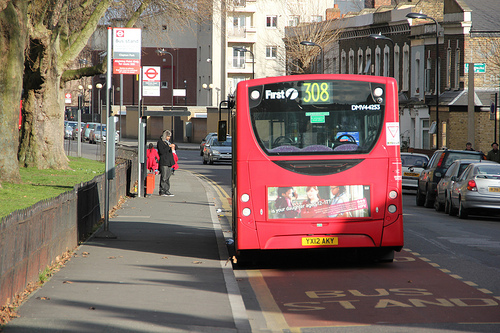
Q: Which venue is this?
A: This is a street.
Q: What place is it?
A: It is a street.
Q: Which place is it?
A: It is a street.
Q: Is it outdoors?
A: Yes, it is outdoors.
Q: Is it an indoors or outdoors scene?
A: It is outdoors.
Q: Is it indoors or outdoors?
A: It is outdoors.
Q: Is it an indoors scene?
A: No, it is outdoors.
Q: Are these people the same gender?
A: No, they are both male and female.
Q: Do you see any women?
A: Yes, there is a woman.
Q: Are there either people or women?
A: Yes, there is a woman.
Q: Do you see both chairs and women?
A: No, there is a woman but no chairs.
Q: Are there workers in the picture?
A: No, there are no workers.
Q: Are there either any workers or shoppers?
A: No, there are no workers or shoppers.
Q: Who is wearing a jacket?
A: The woman is wearing a jacket.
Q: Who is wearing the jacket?
A: The woman is wearing a jacket.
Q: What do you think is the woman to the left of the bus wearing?
A: The woman is wearing a jacket.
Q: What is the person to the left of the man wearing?
A: The woman is wearing a jacket.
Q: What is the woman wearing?
A: The woman is wearing a jacket.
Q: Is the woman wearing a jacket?
A: Yes, the woman is wearing a jacket.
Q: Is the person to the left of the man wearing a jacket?
A: Yes, the woman is wearing a jacket.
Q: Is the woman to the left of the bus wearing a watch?
A: No, the woman is wearing a jacket.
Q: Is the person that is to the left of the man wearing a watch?
A: No, the woman is wearing a jacket.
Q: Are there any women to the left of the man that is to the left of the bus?
A: Yes, there is a woman to the left of the man.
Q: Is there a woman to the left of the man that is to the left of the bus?
A: Yes, there is a woman to the left of the man.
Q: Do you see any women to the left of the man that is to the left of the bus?
A: Yes, there is a woman to the left of the man.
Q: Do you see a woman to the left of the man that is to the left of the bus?
A: Yes, there is a woman to the left of the man.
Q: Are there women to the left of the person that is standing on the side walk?
A: Yes, there is a woman to the left of the man.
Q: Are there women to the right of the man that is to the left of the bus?
A: No, the woman is to the left of the man.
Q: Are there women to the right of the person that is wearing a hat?
A: No, the woman is to the left of the man.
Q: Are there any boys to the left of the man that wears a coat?
A: No, there is a woman to the left of the man.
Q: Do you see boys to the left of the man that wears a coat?
A: No, there is a woman to the left of the man.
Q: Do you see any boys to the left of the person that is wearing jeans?
A: No, there is a woman to the left of the man.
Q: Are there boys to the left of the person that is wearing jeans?
A: No, there is a woman to the left of the man.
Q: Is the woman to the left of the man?
A: Yes, the woman is to the left of the man.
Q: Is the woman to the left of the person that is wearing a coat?
A: Yes, the woman is to the left of the man.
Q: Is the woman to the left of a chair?
A: No, the woman is to the left of the man.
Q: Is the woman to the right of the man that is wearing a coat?
A: No, the woman is to the left of the man.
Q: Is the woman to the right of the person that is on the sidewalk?
A: No, the woman is to the left of the man.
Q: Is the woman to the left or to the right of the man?
A: The woman is to the left of the man.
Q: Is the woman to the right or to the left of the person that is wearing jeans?
A: The woman is to the left of the man.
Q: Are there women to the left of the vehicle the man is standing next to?
A: Yes, there is a woman to the left of the bus.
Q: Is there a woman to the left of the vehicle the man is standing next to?
A: Yes, there is a woman to the left of the bus.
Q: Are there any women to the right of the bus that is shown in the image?
A: No, the woman is to the left of the bus.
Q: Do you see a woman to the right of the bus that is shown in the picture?
A: No, the woman is to the left of the bus.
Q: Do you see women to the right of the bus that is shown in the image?
A: No, the woman is to the left of the bus.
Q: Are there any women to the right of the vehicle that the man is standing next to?
A: No, the woman is to the left of the bus.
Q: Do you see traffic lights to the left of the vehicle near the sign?
A: No, there is a woman to the left of the bus.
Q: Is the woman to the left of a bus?
A: Yes, the woman is to the left of a bus.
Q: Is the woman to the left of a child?
A: No, the woman is to the left of a bus.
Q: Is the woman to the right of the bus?
A: No, the woman is to the left of the bus.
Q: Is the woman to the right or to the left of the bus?
A: The woman is to the left of the bus.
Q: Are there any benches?
A: No, there are no benches.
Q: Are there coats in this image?
A: Yes, there is a coat.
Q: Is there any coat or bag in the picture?
A: Yes, there is a coat.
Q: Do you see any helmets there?
A: No, there are no helmets.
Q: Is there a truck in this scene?
A: No, there are no trucks.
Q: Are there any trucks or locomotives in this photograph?
A: No, there are no trucks or locomotives.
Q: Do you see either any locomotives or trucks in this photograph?
A: No, there are no trucks or locomotives.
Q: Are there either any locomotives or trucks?
A: No, there are no trucks or locomotives.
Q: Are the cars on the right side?
A: Yes, the cars are on the right of the image.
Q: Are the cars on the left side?
A: No, the cars are on the right of the image.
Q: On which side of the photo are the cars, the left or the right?
A: The cars are on the right of the image.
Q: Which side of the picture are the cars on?
A: The cars are on the right of the image.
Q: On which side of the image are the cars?
A: The cars are on the right of the image.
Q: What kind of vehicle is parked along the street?
A: The vehicles are cars.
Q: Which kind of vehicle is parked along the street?
A: The vehicles are cars.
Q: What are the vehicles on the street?
A: The vehicles are cars.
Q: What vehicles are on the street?
A: The vehicles are cars.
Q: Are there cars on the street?
A: Yes, there are cars on the street.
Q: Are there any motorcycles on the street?
A: No, there are cars on the street.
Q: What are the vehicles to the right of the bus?
A: The vehicles are cars.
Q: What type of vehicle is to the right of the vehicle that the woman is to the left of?
A: The vehicles are cars.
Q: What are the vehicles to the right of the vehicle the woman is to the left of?
A: The vehicles are cars.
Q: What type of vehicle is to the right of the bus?
A: The vehicles are cars.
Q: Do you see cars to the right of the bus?
A: Yes, there are cars to the right of the bus.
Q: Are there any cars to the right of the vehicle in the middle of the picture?
A: Yes, there are cars to the right of the bus.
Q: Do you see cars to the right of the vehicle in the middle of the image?
A: Yes, there are cars to the right of the bus.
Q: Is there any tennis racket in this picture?
A: No, there are no rackets.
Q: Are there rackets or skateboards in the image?
A: No, there are no rackets or skateboards.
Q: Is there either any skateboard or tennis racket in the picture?
A: No, there are no rackets or skateboards.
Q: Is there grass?
A: Yes, there is grass.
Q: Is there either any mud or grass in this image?
A: Yes, there is grass.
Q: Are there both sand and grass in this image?
A: No, there is grass but no sand.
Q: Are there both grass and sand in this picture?
A: No, there is grass but no sand.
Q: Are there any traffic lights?
A: No, there are no traffic lights.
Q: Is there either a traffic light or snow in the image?
A: No, there are no traffic lights or snow.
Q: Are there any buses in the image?
A: Yes, there is a bus.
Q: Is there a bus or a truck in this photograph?
A: Yes, there is a bus.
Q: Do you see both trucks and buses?
A: No, there is a bus but no trucks.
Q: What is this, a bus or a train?
A: This is a bus.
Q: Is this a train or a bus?
A: This is a bus.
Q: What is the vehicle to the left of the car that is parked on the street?
A: The vehicle is a bus.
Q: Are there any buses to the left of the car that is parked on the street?
A: Yes, there is a bus to the left of the car.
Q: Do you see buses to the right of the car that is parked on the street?
A: No, the bus is to the left of the car.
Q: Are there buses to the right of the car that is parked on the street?
A: No, the bus is to the left of the car.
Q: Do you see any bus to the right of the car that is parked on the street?
A: No, the bus is to the left of the car.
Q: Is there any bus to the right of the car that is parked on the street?
A: No, the bus is to the left of the car.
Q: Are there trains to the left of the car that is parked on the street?
A: No, there is a bus to the left of the car.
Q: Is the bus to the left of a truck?
A: No, the bus is to the left of the car.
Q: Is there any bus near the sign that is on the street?
A: Yes, there is a bus near the sign.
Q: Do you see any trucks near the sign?
A: No, there is a bus near the sign.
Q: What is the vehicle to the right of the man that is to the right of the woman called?
A: The vehicle is a bus.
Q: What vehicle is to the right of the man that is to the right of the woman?
A: The vehicle is a bus.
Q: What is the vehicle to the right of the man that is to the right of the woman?
A: The vehicle is a bus.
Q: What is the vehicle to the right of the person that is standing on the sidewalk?
A: The vehicle is a bus.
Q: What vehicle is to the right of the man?
A: The vehicle is a bus.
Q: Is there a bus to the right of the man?
A: Yes, there is a bus to the right of the man.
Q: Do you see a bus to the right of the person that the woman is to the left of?
A: Yes, there is a bus to the right of the man.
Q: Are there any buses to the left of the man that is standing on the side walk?
A: No, the bus is to the right of the man.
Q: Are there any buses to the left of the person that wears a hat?
A: No, the bus is to the right of the man.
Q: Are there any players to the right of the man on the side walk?
A: No, there is a bus to the right of the man.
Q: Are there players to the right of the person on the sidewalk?
A: No, there is a bus to the right of the man.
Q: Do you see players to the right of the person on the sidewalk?
A: No, there is a bus to the right of the man.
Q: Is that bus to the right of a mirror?
A: No, the bus is to the right of a man.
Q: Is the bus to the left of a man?
A: No, the bus is to the right of a man.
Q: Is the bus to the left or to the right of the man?
A: The bus is to the right of the man.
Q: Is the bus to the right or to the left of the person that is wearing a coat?
A: The bus is to the right of the man.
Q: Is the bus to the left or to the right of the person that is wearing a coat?
A: The bus is to the right of the man.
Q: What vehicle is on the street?
A: The vehicle is a bus.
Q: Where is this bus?
A: The bus is on the street.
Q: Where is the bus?
A: The bus is on the street.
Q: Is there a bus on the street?
A: Yes, there is a bus on the street.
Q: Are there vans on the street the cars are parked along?
A: No, there is a bus on the street.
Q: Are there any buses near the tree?
A: Yes, there is a bus near the tree.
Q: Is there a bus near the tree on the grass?
A: Yes, there is a bus near the tree.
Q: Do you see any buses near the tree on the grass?
A: Yes, there is a bus near the tree.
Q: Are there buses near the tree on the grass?
A: Yes, there is a bus near the tree.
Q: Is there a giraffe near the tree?
A: No, there is a bus near the tree.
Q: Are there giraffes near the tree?
A: No, there is a bus near the tree.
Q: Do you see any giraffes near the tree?
A: No, there is a bus near the tree.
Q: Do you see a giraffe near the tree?
A: No, there is a bus near the tree.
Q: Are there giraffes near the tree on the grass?
A: No, there is a bus near the tree.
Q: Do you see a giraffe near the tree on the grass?
A: No, there is a bus near the tree.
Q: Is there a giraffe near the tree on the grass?
A: No, there is a bus near the tree.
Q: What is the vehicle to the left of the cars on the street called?
A: The vehicle is a bus.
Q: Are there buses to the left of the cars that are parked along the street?
A: Yes, there is a bus to the left of the cars.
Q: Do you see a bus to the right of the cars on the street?
A: No, the bus is to the left of the cars.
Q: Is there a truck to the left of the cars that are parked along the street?
A: No, there is a bus to the left of the cars.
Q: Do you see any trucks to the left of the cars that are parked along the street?
A: No, there is a bus to the left of the cars.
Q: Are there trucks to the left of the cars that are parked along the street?
A: No, there is a bus to the left of the cars.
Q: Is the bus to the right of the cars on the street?
A: No, the bus is to the left of the cars.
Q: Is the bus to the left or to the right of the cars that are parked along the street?
A: The bus is to the left of the cars.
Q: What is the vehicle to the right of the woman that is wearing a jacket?
A: The vehicle is a bus.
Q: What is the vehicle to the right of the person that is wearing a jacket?
A: The vehicle is a bus.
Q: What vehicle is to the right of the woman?
A: The vehicle is a bus.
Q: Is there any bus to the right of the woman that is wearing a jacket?
A: Yes, there is a bus to the right of the woman.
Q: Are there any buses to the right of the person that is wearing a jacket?
A: Yes, there is a bus to the right of the woman.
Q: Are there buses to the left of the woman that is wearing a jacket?
A: No, the bus is to the right of the woman.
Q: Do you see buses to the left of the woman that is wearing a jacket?
A: No, the bus is to the right of the woman.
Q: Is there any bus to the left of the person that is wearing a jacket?
A: No, the bus is to the right of the woman.